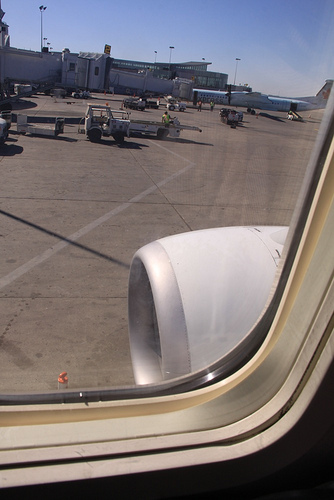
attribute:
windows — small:
[202, 94, 227, 98]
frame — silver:
[129, 252, 183, 382]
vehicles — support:
[118, 88, 163, 113]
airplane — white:
[185, 74, 318, 114]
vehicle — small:
[85, 102, 131, 147]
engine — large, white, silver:
[104, 196, 295, 407]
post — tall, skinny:
[38, 2, 48, 51]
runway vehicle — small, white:
[79, 98, 138, 152]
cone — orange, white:
[58, 370, 69, 389]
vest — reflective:
[160, 112, 170, 123]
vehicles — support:
[120, 91, 193, 122]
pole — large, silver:
[30, 13, 59, 59]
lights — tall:
[38, 4, 45, 53]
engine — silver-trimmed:
[125, 223, 288, 381]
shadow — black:
[0, 207, 131, 270]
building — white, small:
[35, 35, 154, 125]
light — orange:
[105, 103, 112, 109]